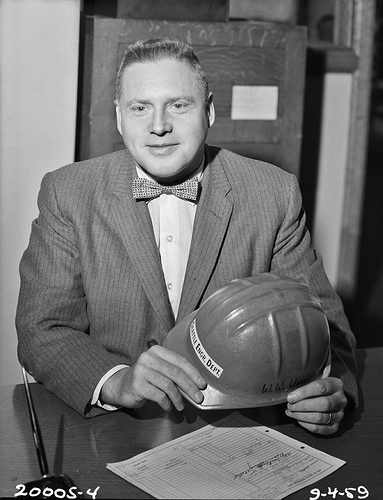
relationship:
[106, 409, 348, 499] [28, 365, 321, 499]
invoice on desk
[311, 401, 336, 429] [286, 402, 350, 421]
band on finger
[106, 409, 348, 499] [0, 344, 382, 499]
invoice on desk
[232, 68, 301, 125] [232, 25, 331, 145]
label on box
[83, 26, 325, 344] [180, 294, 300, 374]
man holding hat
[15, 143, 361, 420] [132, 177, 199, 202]
blazer has bow